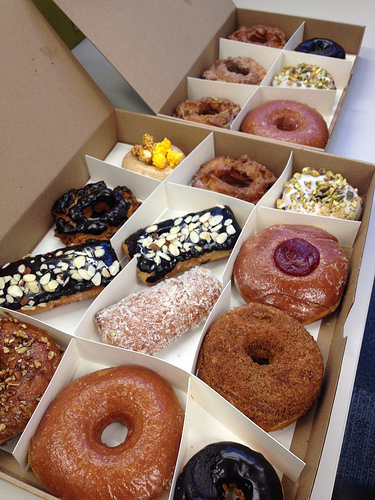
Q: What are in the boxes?
A: Donuts.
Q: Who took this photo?
A: The baker.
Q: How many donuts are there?
A: Three dozen.